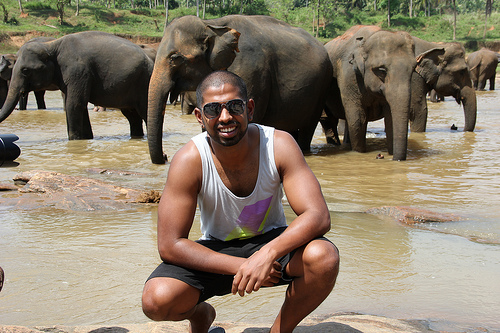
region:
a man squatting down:
[120, 62, 347, 332]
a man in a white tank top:
[142, 67, 340, 323]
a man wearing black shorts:
[127, 65, 349, 330]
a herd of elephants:
[16, 17, 496, 180]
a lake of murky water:
[20, 48, 484, 328]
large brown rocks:
[8, 166, 498, 242]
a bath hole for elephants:
[12, 15, 497, 328]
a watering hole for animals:
[10, 30, 497, 332]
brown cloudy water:
[6, 98, 498, 330]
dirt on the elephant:
[142, 38, 200, 133]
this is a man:
[158, 73, 325, 330]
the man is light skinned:
[287, 172, 310, 188]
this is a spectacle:
[193, 100, 247, 116]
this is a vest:
[203, 195, 240, 219]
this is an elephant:
[218, 14, 290, 80]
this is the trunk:
[391, 90, 404, 147]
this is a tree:
[317, 4, 337, 37]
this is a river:
[398, 234, 440, 291]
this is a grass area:
[118, 19, 140, 29]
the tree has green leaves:
[400, 16, 420, 25]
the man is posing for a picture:
[126, 39, 421, 270]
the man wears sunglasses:
[80, 36, 412, 313]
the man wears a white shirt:
[139, 51, 346, 249]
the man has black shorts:
[120, 53, 387, 310]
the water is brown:
[369, 165, 479, 249]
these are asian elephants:
[33, 39, 440, 132]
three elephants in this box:
[13, 31, 422, 163]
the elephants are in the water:
[10, 32, 487, 211]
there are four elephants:
[11, 36, 483, 167]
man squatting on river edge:
[132, 50, 359, 332]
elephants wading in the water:
[0, 17, 499, 178]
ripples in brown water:
[36, 155, 148, 240]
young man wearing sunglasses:
[184, 76, 266, 166]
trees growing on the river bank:
[6, 5, 499, 59]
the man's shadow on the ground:
[90, 314, 385, 331]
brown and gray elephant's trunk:
[141, 32, 173, 169]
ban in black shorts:
[168, 71, 319, 330]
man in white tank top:
[176, 77, 316, 316]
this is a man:
[156, 58, 327, 331]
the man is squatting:
[148, 62, 341, 331]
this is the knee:
[303, 241, 339, 289]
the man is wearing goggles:
[202, 95, 245, 122]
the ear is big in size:
[202, 20, 242, 68]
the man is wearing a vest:
[203, 186, 273, 238]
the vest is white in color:
[214, 199, 266, 235]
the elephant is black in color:
[236, 25, 313, 76]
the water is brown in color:
[50, 164, 110, 224]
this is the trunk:
[143, 57, 173, 162]